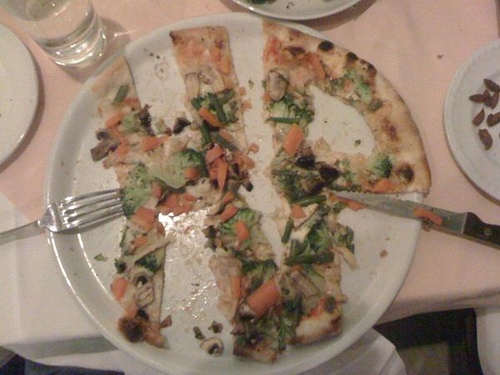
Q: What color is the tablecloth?
A: Pink.